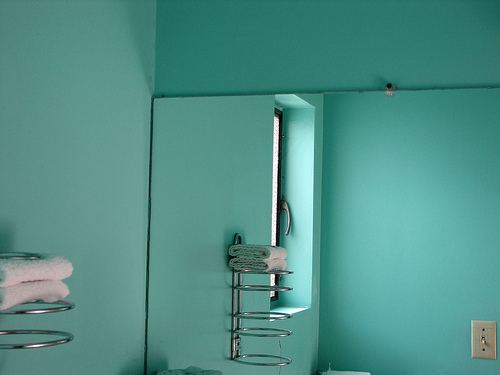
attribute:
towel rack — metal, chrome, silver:
[0, 252, 75, 350]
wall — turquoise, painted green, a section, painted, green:
[0, 0, 155, 375]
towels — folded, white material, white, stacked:
[0, 256, 74, 311]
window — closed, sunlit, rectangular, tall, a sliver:
[270, 111, 283, 301]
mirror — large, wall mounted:
[145, 86, 498, 374]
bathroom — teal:
[0, 0, 499, 374]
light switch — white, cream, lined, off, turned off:
[470, 320, 496, 361]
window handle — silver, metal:
[278, 200, 293, 236]